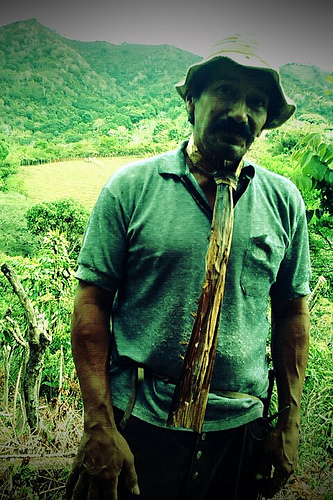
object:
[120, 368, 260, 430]
rope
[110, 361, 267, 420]
waist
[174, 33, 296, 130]
hat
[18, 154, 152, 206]
grassy field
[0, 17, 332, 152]
mountains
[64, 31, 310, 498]
man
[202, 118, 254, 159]
mustache